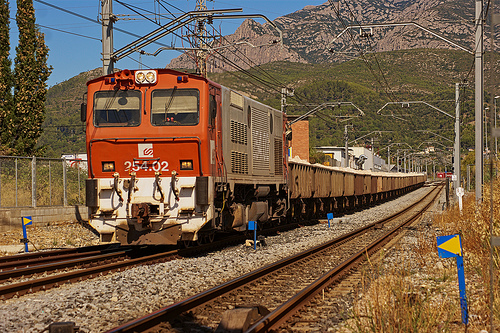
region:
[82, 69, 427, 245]
Train on the tracks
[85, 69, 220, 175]
Front of train is orange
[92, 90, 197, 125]
Front windows of train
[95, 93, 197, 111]
Blinds in the windows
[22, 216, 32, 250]
Blue and yellow sign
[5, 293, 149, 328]
Rocks between the tracks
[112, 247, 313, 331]
Tracks are rust colored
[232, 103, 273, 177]
Vents on side of train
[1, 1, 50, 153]
Yellow and green trees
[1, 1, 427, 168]
Cables above the train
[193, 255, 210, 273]
part of a ground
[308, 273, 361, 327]
edge of a rail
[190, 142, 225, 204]
edge of a train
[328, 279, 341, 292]
edge of a rail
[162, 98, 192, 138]
part of a window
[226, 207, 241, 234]
part of a window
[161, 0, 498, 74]
tall rocky mountain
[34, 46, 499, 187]
tree covered hill top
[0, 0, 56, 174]
tall green and brown bushes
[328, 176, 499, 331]
section of dead grass and weeds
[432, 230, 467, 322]
metal blue and yellow flag sign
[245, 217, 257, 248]
metal blue flag sign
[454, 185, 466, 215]
white paddle sign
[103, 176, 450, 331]
long, rusty, and empty railroad tracks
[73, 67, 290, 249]
orange and cream colored train engine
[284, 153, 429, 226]
cargo train cars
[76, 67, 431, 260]
electrically powered train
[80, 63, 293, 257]
front engine car of long train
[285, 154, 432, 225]
over 20 half height brown box cars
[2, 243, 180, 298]
two train tracks side by side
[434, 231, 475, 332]
blue and yellow short signal pole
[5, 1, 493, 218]
overhead electrical wires and supports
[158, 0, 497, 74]
steep mountain with very little vegetation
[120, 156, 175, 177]
engine car identifying number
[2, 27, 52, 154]
two tall skinny trees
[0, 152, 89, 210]
metal chainlink fence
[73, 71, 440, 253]
train on the tracks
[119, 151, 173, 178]
white number on the side of the train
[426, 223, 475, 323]
blue and yellow sign next to the train tracks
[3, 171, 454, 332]
two parallel sets of train tracks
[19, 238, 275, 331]
gravel between the tracks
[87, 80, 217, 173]
front of the train is burnt orange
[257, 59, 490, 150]
hillside is covered in green grass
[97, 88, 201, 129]
two windows on the train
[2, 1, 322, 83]
bright blue sky with no clouds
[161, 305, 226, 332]
shadow on the tracks